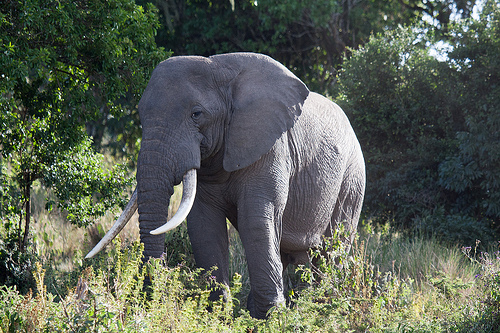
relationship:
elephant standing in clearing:
[81, 51, 366, 320] [1, 151, 496, 332]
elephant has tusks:
[81, 51, 366, 320] [83, 168, 196, 261]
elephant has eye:
[81, 51, 366, 320] [189, 109, 205, 120]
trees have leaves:
[0, 2, 495, 241] [0, 0, 499, 248]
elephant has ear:
[81, 51, 366, 320] [210, 51, 311, 174]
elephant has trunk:
[81, 51, 366, 320] [136, 121, 178, 301]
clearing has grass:
[1, 151, 496, 332] [1, 155, 496, 331]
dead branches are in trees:
[275, 18, 358, 72] [0, 2, 495, 241]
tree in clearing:
[1, 92, 95, 274] [1, 151, 496, 332]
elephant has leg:
[81, 51, 366, 320] [235, 191, 285, 321]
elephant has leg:
[81, 51, 366, 320] [186, 183, 235, 312]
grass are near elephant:
[1, 167, 500, 333] [81, 51, 366, 320]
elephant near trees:
[81, 51, 366, 320] [0, 2, 495, 241]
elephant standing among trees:
[81, 51, 366, 320] [0, 2, 495, 241]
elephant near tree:
[81, 51, 366, 320] [1, 92, 95, 274]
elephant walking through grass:
[81, 51, 366, 320] [1, 155, 496, 331]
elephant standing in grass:
[81, 51, 366, 320] [1, 155, 496, 331]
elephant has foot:
[81, 51, 366, 320] [245, 288, 291, 320]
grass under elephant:
[1, 155, 496, 331] [81, 51, 366, 320]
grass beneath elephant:
[1, 155, 496, 331] [81, 51, 366, 320]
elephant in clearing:
[81, 51, 366, 320] [1, 151, 496, 332]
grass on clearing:
[1, 155, 496, 331] [1, 151, 496, 332]